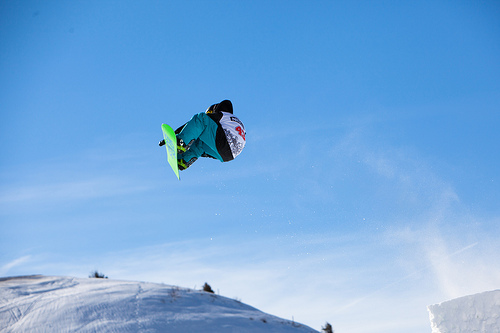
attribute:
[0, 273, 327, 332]
snow — white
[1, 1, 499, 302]
sky — blue, clear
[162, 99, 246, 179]
snowboarder — performing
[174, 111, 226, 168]
pants — blue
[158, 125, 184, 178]
snowboard — green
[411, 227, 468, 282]
clouds — white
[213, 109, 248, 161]
jacket — white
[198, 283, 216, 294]
tree — green